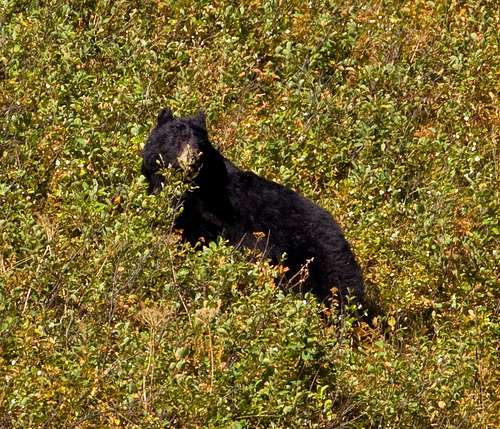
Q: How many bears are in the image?
A: 1.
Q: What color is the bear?
A: Black.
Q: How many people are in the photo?
A: 0.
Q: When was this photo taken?
A: Daytime.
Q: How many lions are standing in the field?
A: 0.